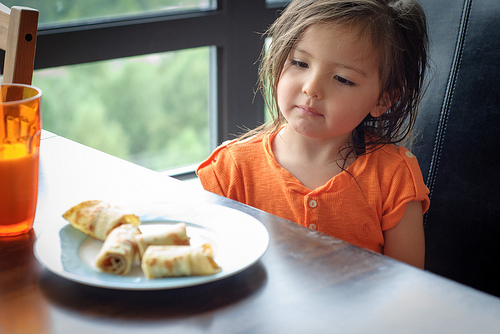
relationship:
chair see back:
[0, 4, 39, 82] [2, 4, 42, 77]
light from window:
[261, 263, 408, 332] [9, 4, 273, 151]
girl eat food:
[189, 0, 438, 270] [54, 190, 230, 288]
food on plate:
[62, 198, 222, 278] [33, 195, 270, 292]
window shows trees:
[0, 3, 267, 163] [50, 59, 214, 157]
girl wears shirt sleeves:
[189, 0, 438, 270] [371, 135, 432, 231]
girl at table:
[189, 0, 438, 270] [0, 129, 497, 330]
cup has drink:
[1, 74, 44, 246] [0, 142, 39, 238]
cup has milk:
[0, 82, 42, 248] [0, 142, 36, 223]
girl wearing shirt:
[189, 0, 438, 270] [194, 122, 431, 255]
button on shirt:
[308, 200, 319, 208] [194, 122, 431, 255]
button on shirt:
[307, 215, 321, 232] [194, 122, 431, 255]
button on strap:
[285, 189, 355, 219] [407, 156, 449, 201]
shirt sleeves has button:
[371, 138, 432, 231] [285, 189, 355, 219]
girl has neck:
[189, 0, 438, 270] [266, 100, 371, 173]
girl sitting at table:
[198, 0, 429, 265] [0, 129, 497, 330]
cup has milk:
[0, 82, 42, 248] [0, 138, 39, 222]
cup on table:
[0, 82, 42, 248] [0, 129, 497, 330]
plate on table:
[28, 190, 275, 299] [0, 129, 497, 330]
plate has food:
[30, 196, 270, 290] [50, 193, 229, 281]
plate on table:
[30, 196, 270, 290] [0, 129, 497, 330]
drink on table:
[1, 81, 43, 243] [0, 129, 497, 330]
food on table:
[62, 198, 222, 278] [0, 129, 497, 330]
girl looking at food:
[189, 0, 438, 270] [62, 198, 222, 278]